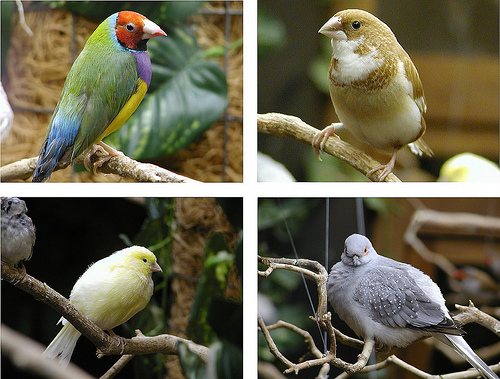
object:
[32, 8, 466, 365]
birds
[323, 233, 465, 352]
feathers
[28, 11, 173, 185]
bird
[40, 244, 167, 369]
bird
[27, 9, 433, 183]
birds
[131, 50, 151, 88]
feathers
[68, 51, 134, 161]
wing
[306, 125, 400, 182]
tallons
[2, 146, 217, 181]
branch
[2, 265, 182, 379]
branch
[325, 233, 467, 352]
bird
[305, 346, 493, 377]
branch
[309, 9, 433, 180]
bird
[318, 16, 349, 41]
beak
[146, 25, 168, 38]
beak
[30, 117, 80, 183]
feathers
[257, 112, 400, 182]
branch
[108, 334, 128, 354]
claws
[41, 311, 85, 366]
tail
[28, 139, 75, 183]
tail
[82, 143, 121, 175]
claws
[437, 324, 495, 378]
tail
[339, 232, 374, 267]
head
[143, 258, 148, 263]
eye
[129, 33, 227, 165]
leaf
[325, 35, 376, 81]
patch